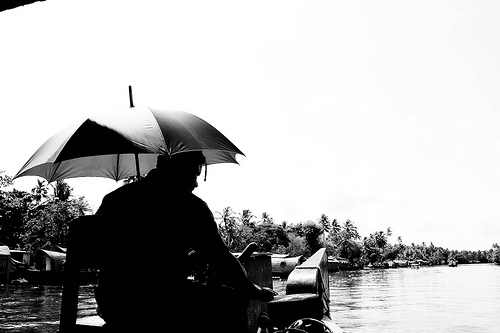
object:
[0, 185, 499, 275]
trees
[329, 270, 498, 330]
water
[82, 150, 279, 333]
man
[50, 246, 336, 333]
boat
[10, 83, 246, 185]
umbrella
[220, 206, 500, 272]
houses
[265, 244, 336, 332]
front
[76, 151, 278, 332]
person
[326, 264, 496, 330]
river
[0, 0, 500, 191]
sky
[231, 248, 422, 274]
homes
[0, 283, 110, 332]
ripples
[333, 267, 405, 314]
reflections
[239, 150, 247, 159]
spoke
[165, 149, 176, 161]
spoke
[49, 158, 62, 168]
spoke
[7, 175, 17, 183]
spoke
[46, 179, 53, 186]
spoke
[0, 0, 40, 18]
building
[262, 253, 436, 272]
buildings